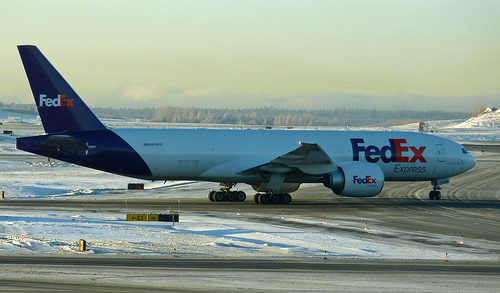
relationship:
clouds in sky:
[109, 87, 475, 109] [0, 1, 498, 111]